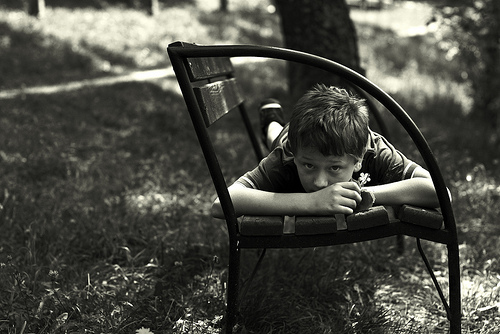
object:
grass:
[0, 0, 499, 116]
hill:
[0, 0, 457, 99]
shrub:
[405, 0, 499, 131]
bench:
[165, 39, 465, 333]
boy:
[207, 82, 452, 216]